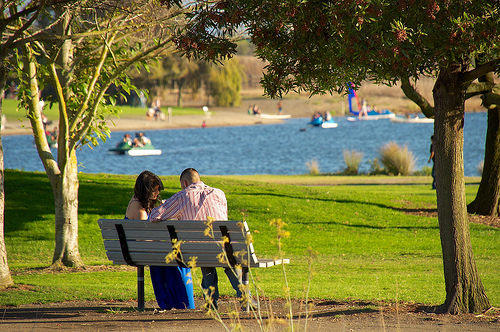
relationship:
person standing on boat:
[358, 97, 370, 109] [349, 106, 393, 121]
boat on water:
[106, 139, 162, 159] [194, 136, 294, 160]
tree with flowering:
[244, 11, 498, 318] [355, 6, 421, 63]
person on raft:
[132, 131, 151, 148] [106, 143, 166, 159]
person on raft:
[120, 133, 133, 147] [106, 143, 166, 159]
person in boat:
[120, 132, 130, 147] [110, 141, 162, 158]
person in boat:
[128, 135, 144, 149] [110, 141, 162, 158]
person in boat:
[132, 131, 151, 148] [110, 141, 162, 158]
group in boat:
[118, 132, 151, 147] [111, 142, 170, 159]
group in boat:
[312, 109, 335, 120] [309, 116, 340, 129]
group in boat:
[362, 97, 385, 114] [366, 110, 402, 122]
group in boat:
[247, 100, 264, 114] [257, 111, 294, 122]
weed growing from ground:
[268, 213, 302, 329] [6, 174, 497, 329]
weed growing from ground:
[292, 242, 319, 330] [6, 174, 497, 329]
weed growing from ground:
[200, 215, 260, 330] [6, 174, 497, 329]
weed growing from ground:
[164, 239, 234, 330] [6, 174, 497, 329]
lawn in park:
[0, 93, 498, 313] [0, 97, 498, 327]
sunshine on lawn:
[28, 182, 498, 302] [0, 93, 498, 313]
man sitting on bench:
[146, 169, 260, 312] [97, 218, 291, 311]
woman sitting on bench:
[122, 170, 193, 311] [97, 218, 291, 311]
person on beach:
[252, 103, 262, 117] [0, 97, 290, 131]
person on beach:
[274, 98, 284, 115] [0, 97, 290, 131]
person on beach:
[198, 106, 208, 128] [0, 97, 290, 131]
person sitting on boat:
[132, 131, 151, 148] [107, 141, 162, 161]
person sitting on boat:
[120, 133, 133, 147] [107, 141, 162, 161]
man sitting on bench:
[150, 167, 261, 312] [98, 219, 289, 311]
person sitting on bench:
[122, 168, 194, 310] [98, 219, 289, 311]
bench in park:
[98, 219, 289, 311] [0, 97, 498, 327]